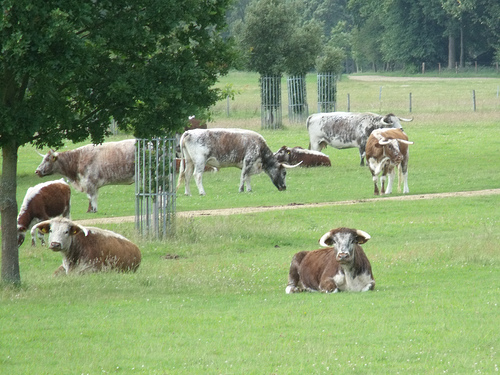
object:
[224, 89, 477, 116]
fence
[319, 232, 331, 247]
horns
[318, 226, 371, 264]
head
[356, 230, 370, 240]
horns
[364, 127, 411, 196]
animal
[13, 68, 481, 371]
grass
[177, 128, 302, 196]
bull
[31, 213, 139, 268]
bull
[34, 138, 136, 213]
bull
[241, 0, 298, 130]
trees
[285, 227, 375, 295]
bull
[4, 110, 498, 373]
field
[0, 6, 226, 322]
tree